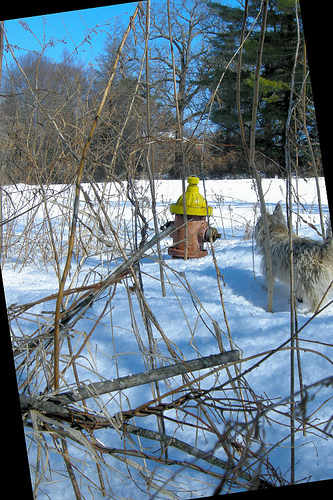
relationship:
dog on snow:
[256, 200, 330, 317] [1, 175, 331, 499]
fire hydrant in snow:
[160, 175, 220, 263] [1, 175, 331, 499]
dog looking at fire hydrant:
[256, 200, 330, 317] [160, 175, 220, 263]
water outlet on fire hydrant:
[205, 226, 222, 243] [160, 175, 220, 263]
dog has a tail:
[256, 200, 330, 317] [321, 215, 331, 256]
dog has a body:
[256, 200, 330, 317] [272, 233, 321, 295]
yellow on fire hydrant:
[170, 176, 212, 216] [160, 175, 220, 263]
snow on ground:
[1, 175, 331, 499] [1, 174, 331, 498]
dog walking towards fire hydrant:
[256, 200, 330, 317] [160, 175, 220, 263]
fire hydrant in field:
[160, 175, 220, 263] [1, 0, 331, 498]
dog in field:
[256, 200, 330, 317] [1, 0, 331, 498]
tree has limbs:
[123, 0, 230, 180] [121, 0, 236, 181]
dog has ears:
[256, 200, 330, 317] [259, 199, 284, 217]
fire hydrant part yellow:
[160, 175, 220, 263] [170, 176, 212, 216]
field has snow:
[1, 0, 331, 498] [1, 175, 331, 499]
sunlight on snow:
[1, 0, 331, 499] [1, 175, 331, 499]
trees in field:
[2, 0, 330, 276] [1, 0, 331, 498]